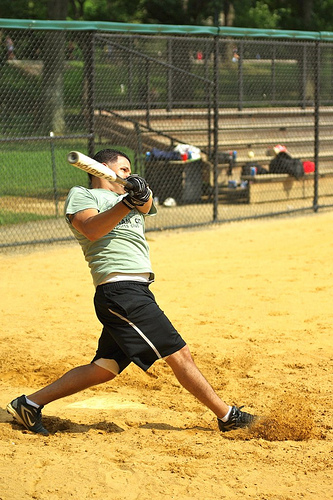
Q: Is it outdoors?
A: Yes, it is outdoors.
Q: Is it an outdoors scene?
A: Yes, it is outdoors.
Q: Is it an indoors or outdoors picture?
A: It is outdoors.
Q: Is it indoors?
A: No, it is outdoors.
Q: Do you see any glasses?
A: No, there are no glasses.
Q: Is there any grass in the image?
A: Yes, there is grass.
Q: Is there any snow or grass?
A: Yes, there is grass.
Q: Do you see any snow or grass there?
A: Yes, there is grass.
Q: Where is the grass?
A: The grass is on the ground.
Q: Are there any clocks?
A: No, there are no clocks.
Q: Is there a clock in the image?
A: No, there are no clocks.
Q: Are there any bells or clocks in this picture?
A: No, there are no clocks or bells.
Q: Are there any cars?
A: No, there are no cars.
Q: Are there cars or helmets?
A: No, there are no cars or helmets.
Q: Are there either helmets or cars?
A: No, there are no cars or helmets.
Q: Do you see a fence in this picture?
A: Yes, there is a fence.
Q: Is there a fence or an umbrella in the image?
A: Yes, there is a fence.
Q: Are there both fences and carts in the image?
A: No, there is a fence but no carts.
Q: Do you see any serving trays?
A: No, there are no serving trays.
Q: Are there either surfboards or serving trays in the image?
A: No, there are no serving trays or surfboards.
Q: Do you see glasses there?
A: No, there are no glasses.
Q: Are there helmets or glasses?
A: No, there are no glasses or helmets.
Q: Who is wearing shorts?
A: The man is wearing shorts.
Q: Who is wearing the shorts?
A: The man is wearing shorts.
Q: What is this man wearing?
A: The man is wearing shorts.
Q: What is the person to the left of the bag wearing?
A: The man is wearing shorts.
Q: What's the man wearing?
A: The man is wearing shorts.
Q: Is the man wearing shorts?
A: Yes, the man is wearing shorts.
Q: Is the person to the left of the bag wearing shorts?
A: Yes, the man is wearing shorts.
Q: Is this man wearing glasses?
A: No, the man is wearing shorts.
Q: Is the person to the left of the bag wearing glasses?
A: No, the man is wearing shorts.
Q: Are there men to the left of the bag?
A: Yes, there is a man to the left of the bag.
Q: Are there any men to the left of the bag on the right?
A: Yes, there is a man to the left of the bag.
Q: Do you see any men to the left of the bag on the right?
A: Yes, there is a man to the left of the bag.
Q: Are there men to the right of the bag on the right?
A: No, the man is to the left of the bag.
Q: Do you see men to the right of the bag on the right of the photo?
A: No, the man is to the left of the bag.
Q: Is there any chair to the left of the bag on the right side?
A: No, there is a man to the left of the bag.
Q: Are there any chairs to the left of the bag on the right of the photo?
A: No, there is a man to the left of the bag.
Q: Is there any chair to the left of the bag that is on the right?
A: No, there is a man to the left of the bag.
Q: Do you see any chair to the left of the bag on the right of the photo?
A: No, there is a man to the left of the bag.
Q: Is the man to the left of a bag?
A: Yes, the man is to the left of a bag.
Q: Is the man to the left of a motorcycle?
A: No, the man is to the left of a bag.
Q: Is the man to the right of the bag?
A: No, the man is to the left of the bag.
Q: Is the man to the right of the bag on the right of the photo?
A: No, the man is to the left of the bag.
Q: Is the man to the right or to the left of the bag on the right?
A: The man is to the left of the bag.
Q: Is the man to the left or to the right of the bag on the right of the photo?
A: The man is to the left of the bag.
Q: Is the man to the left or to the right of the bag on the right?
A: The man is to the left of the bag.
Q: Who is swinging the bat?
A: The man is swinging the bat.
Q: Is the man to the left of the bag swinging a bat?
A: Yes, the man is swinging a bat.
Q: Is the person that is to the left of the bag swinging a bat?
A: Yes, the man is swinging a bat.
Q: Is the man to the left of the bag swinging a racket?
A: No, the man is swinging a bat.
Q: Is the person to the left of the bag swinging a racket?
A: No, the man is swinging a bat.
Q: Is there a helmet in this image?
A: No, there are no helmets.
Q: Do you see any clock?
A: No, there are no clocks.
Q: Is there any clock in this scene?
A: No, there are no clocks.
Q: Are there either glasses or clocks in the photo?
A: No, there are no clocks or glasses.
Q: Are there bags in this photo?
A: Yes, there is a bag.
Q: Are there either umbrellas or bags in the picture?
A: Yes, there is a bag.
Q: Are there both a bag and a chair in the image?
A: No, there is a bag but no chairs.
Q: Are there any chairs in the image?
A: No, there are no chairs.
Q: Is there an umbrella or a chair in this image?
A: No, there are no chairs or umbrellas.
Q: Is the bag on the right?
A: Yes, the bag is on the right of the image.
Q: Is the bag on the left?
A: No, the bag is on the right of the image.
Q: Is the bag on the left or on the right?
A: The bag is on the right of the image.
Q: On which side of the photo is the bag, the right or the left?
A: The bag is on the right of the image.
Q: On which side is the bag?
A: The bag is on the right of the image.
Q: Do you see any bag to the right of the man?
A: Yes, there is a bag to the right of the man.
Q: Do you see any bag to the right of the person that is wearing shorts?
A: Yes, there is a bag to the right of the man.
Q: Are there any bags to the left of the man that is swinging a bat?
A: No, the bag is to the right of the man.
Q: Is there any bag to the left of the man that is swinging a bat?
A: No, the bag is to the right of the man.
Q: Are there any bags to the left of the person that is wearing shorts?
A: No, the bag is to the right of the man.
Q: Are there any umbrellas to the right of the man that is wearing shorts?
A: No, there is a bag to the right of the man.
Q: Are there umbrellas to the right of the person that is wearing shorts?
A: No, there is a bag to the right of the man.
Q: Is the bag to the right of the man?
A: Yes, the bag is to the right of the man.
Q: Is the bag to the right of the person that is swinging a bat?
A: Yes, the bag is to the right of the man.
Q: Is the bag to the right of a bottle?
A: No, the bag is to the right of the man.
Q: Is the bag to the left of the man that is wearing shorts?
A: No, the bag is to the right of the man.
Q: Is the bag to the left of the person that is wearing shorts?
A: No, the bag is to the right of the man.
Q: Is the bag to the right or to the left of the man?
A: The bag is to the right of the man.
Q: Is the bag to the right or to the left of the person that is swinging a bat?
A: The bag is to the right of the man.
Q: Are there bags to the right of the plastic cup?
A: Yes, there is a bag to the right of the cup.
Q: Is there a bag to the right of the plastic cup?
A: Yes, there is a bag to the right of the cup.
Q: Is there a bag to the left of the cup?
A: No, the bag is to the right of the cup.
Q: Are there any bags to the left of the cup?
A: No, the bag is to the right of the cup.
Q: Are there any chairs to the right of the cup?
A: No, there is a bag to the right of the cup.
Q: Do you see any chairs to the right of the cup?
A: No, there is a bag to the right of the cup.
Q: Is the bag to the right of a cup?
A: Yes, the bag is to the right of a cup.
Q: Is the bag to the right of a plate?
A: No, the bag is to the right of a cup.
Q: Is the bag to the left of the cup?
A: No, the bag is to the right of the cup.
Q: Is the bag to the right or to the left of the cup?
A: The bag is to the right of the cup.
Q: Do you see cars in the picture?
A: No, there are no cars.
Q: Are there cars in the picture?
A: No, there are no cars.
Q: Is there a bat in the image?
A: Yes, there is a bat.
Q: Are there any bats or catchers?
A: Yes, there is a bat.